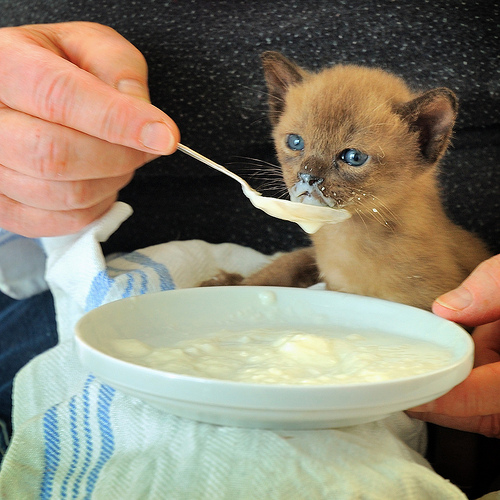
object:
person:
[0, 0, 500, 432]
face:
[278, 129, 379, 206]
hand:
[0, 16, 183, 239]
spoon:
[157, 121, 355, 234]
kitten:
[236, 49, 499, 286]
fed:
[290, 175, 337, 217]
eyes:
[333, 144, 372, 170]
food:
[111, 329, 458, 379]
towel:
[1, 418, 471, 500]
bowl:
[72, 284, 483, 435]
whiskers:
[353, 207, 369, 230]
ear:
[398, 85, 462, 171]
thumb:
[50, 20, 153, 106]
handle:
[176, 143, 251, 186]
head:
[262, 48, 458, 218]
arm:
[195, 247, 325, 294]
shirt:
[1, 1, 500, 255]